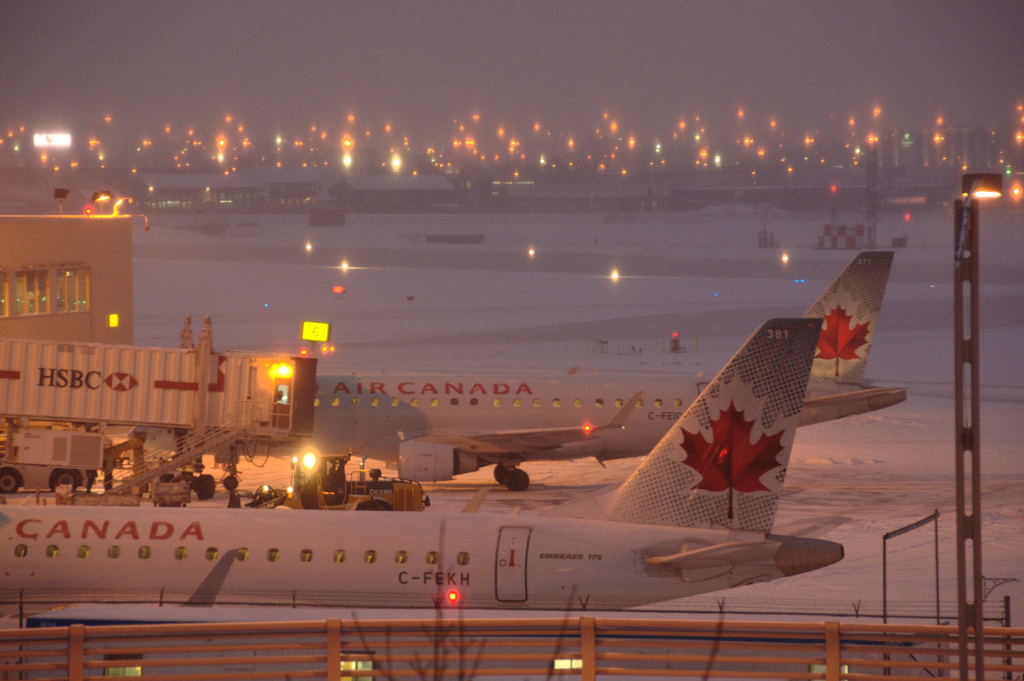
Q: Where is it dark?
A: Top of the photo.